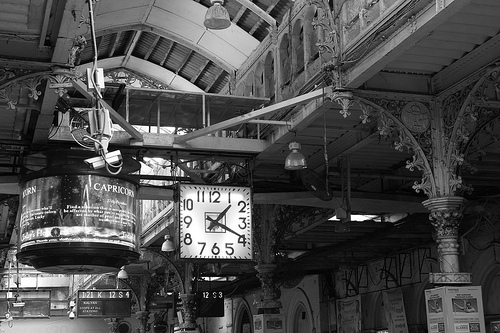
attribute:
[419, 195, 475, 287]
pillar — large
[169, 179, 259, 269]
clock — square shaped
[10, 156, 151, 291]
billboard — circular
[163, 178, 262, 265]
clock face — square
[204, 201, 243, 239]
hands — black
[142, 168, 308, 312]
clock — white , black 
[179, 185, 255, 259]
face — clock's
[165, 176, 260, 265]
face — clock's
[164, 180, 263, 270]
face — clock's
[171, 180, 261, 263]
face — clock's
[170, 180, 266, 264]
clock — white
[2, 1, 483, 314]
photo — indoors, black, white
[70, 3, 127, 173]
camera — in foreground, recording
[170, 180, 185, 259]
frame — black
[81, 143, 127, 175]
camera — white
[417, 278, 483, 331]
posters — in foreground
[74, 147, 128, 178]
camera — side view